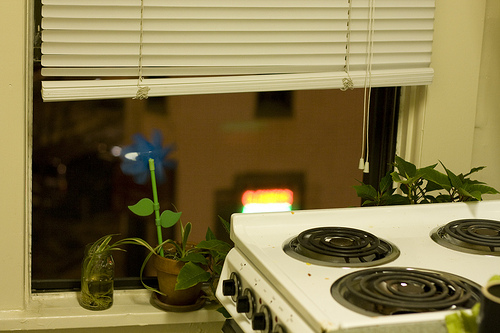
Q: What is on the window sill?
A: Fake blue flower.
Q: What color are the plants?
A: Green.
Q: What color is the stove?
A: White.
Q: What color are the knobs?
A: Black.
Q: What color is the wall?
A: White.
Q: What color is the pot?
A: Brown.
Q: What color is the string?
A: White.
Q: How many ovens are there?
A: One.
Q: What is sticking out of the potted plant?
A: A pinwheel.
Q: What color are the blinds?
A: White.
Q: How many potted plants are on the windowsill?
A: Three.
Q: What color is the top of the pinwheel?
A: Blue.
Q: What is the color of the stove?
A: White.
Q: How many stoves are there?
A: 1.